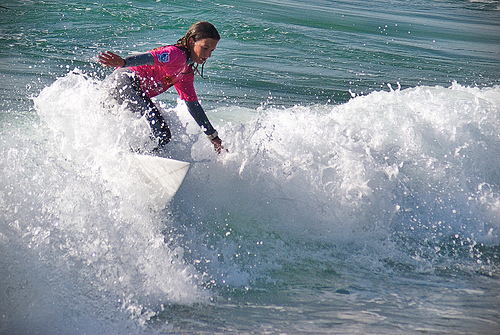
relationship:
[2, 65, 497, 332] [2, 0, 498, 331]
splash in water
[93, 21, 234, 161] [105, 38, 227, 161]
surfer wearing wetsuit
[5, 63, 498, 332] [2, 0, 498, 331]
foam in water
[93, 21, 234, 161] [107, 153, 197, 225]
surfer on surfboard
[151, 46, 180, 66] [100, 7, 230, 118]
logo on shirt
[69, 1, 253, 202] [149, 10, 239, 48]
surfer has hair